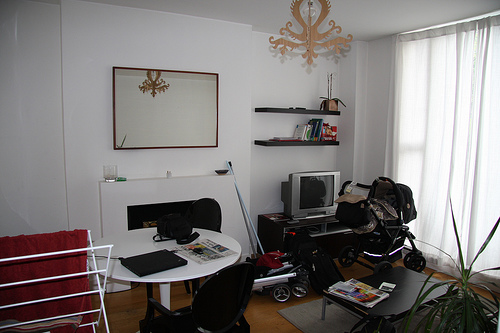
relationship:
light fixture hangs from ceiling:
[267, 2, 352, 62] [97, 1, 498, 41]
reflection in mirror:
[137, 73, 173, 96] [117, 70, 217, 148]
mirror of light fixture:
[117, 70, 217, 148] [272, 8, 352, 72]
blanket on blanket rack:
[2, 226, 102, 329] [0, 233, 115, 331]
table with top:
[80, 224, 240, 317] [88, 227, 240, 282]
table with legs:
[321, 265, 458, 332] [318, 294, 330, 323]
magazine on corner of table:
[333, 276, 379, 312] [287, 271, 437, 322]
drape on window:
[375, 14, 497, 271] [394, 30, 498, 285]